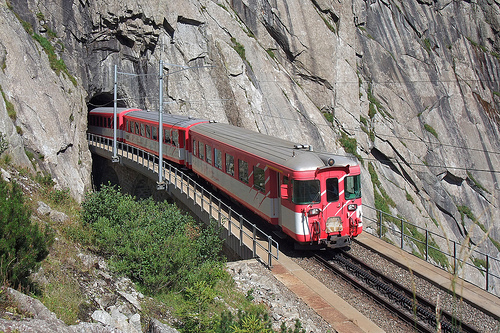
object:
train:
[85, 103, 367, 255]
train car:
[89, 106, 142, 141]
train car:
[122, 110, 209, 165]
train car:
[188, 120, 362, 248]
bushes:
[81, 181, 314, 333]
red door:
[321, 169, 346, 234]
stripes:
[337, 189, 350, 198]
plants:
[334, 131, 366, 172]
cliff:
[0, 0, 499, 293]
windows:
[287, 178, 321, 204]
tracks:
[313, 249, 497, 333]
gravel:
[317, 253, 499, 332]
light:
[309, 208, 321, 220]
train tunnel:
[82, 90, 130, 158]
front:
[290, 161, 362, 251]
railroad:
[86, 101, 499, 333]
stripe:
[189, 155, 314, 234]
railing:
[86, 131, 282, 267]